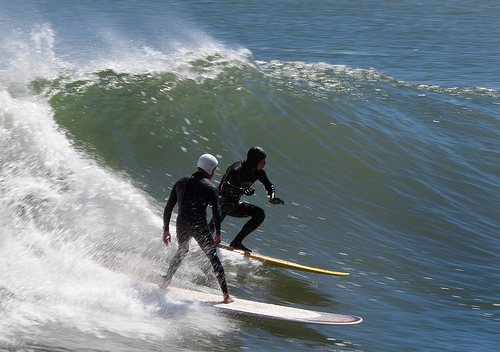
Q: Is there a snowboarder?
A: No, there are no snowboarders.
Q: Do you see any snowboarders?
A: No, there are no snowboarders.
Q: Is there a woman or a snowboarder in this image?
A: No, there are no snowboarders or women.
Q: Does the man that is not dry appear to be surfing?
A: Yes, the man is surfing.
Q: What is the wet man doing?
A: The man is surfing.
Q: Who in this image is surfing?
A: The man is surfing.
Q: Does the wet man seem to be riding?
A: No, the man is surfing.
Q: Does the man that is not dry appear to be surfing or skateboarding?
A: The man is surfing.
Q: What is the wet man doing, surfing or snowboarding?
A: The man is surfing.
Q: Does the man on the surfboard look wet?
A: Yes, the man is wet.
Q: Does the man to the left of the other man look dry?
A: No, the man is wet.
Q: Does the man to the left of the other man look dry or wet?
A: The man is wet.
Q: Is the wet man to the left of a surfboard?
A: Yes, the man is to the left of a surfboard.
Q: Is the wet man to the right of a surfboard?
A: No, the man is to the left of a surfboard.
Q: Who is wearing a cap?
A: The man is wearing a cap.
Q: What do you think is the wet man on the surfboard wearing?
A: The man is wearing a cap.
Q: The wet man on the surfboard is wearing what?
A: The man is wearing a cap.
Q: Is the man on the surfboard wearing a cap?
A: Yes, the man is wearing a cap.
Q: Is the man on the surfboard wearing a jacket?
A: No, the man is wearing a cap.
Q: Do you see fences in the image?
A: No, there are no fences.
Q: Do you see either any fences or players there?
A: No, there are no fences or players.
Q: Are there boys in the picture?
A: No, there are no boys.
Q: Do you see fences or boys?
A: No, there are no boys or fences.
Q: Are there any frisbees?
A: No, there are no frisbees.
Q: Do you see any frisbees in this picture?
A: No, there are no frisbees.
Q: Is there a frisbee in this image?
A: No, there are no frisbees.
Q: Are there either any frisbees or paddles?
A: No, there are no frisbees or paddles.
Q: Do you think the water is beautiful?
A: Yes, the water is beautiful.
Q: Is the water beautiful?
A: Yes, the water is beautiful.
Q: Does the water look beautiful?
A: Yes, the water is beautiful.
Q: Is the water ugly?
A: No, the water is beautiful.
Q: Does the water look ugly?
A: No, the water is beautiful.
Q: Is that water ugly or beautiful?
A: The water is beautiful.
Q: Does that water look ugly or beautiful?
A: The water is beautiful.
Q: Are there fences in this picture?
A: No, there are no fences.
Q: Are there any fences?
A: No, there are no fences.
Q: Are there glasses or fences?
A: No, there are no fences or glasses.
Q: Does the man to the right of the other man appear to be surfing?
A: Yes, the man is surfing.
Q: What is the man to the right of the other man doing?
A: The man is surfing.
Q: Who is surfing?
A: The man is surfing.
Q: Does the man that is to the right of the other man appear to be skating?
A: No, the man is surfing.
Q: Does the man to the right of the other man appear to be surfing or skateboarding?
A: The man is surfing.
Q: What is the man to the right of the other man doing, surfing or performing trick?
A: The man is surfing.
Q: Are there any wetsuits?
A: Yes, there is a wetsuit.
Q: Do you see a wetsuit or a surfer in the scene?
A: Yes, there is a wetsuit.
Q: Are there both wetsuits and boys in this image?
A: No, there is a wetsuit but no boys.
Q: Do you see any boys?
A: No, there are no boys.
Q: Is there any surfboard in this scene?
A: Yes, there is a surfboard.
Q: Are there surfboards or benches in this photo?
A: Yes, there is a surfboard.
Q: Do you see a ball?
A: No, there are no balls.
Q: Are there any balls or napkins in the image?
A: No, there are no balls or napkins.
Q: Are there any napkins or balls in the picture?
A: No, there are no balls or napkins.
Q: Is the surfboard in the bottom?
A: Yes, the surfboard is in the bottom of the image.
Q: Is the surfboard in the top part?
A: No, the surfboard is in the bottom of the image.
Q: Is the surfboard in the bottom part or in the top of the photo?
A: The surfboard is in the bottom of the image.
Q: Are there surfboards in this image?
A: Yes, there is a surfboard.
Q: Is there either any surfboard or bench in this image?
A: Yes, there is a surfboard.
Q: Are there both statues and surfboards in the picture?
A: No, there is a surfboard but no statues.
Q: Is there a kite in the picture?
A: No, there are no kites.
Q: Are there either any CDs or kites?
A: No, there are no kites or cds.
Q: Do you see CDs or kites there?
A: No, there are no kites or cds.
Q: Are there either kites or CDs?
A: No, there are no kites or cds.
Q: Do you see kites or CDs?
A: No, there are no kites or cds.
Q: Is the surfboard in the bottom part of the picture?
A: Yes, the surfboard is in the bottom of the image.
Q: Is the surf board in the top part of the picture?
A: No, the surf board is in the bottom of the image.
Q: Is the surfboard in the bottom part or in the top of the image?
A: The surfboard is in the bottom of the image.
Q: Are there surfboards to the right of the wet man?
A: Yes, there is a surfboard to the right of the man.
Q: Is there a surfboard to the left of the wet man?
A: No, the surfboard is to the right of the man.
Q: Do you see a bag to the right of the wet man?
A: No, there is a surfboard to the right of the man.